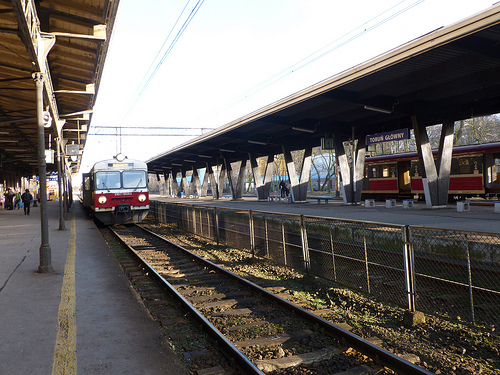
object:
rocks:
[260, 327, 279, 338]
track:
[107, 215, 438, 375]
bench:
[306, 193, 343, 205]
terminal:
[19, 87, 500, 375]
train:
[329, 143, 498, 204]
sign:
[107, 162, 134, 167]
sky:
[94, 0, 499, 73]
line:
[53, 205, 83, 374]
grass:
[309, 293, 328, 307]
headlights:
[97, 195, 107, 205]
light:
[136, 193, 148, 203]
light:
[112, 152, 127, 162]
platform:
[0, 243, 123, 375]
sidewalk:
[1, 200, 192, 374]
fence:
[147, 199, 499, 331]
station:
[1, 2, 191, 374]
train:
[78, 152, 150, 225]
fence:
[253, 212, 308, 273]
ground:
[1, 201, 188, 373]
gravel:
[232, 318, 282, 338]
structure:
[288, 5, 500, 135]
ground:
[0, 325, 500, 375]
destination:
[108, 163, 134, 167]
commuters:
[21, 188, 33, 216]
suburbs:
[39, 55, 462, 366]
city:
[0, 0, 500, 375]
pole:
[32, 61, 52, 276]